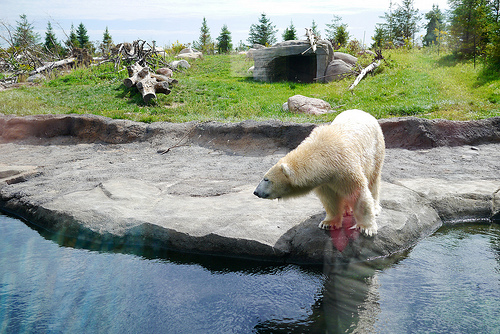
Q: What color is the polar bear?
A: White.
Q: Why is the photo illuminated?
A: Sunlight.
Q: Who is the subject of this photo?
A: The polar bear.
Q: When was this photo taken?
A: During the day.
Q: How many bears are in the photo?
A: One.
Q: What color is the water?
A: Blue.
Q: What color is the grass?
A: Green.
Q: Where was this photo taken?
A: Water.